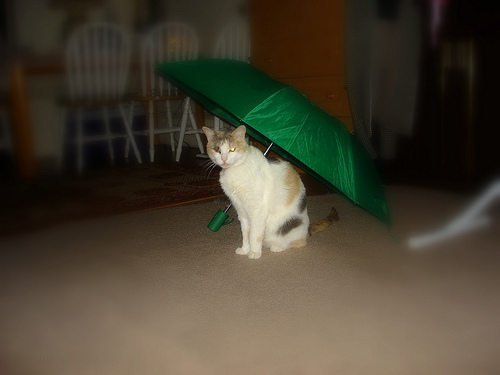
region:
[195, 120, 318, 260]
white cat with red and grey spots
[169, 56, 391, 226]
a bright kelly green umbrella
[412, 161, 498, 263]
front leg of an ironing board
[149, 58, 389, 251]
cat sits under an umbrella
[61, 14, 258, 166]
white side chairs with natural wood seats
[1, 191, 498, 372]
a beige area rug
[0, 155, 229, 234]
a red patterned area rug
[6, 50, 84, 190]
the end of a dining table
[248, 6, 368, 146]
a chest of drawers with wood knobs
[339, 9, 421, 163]
a grey jacket on a hanger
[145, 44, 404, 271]
a cat under an umbrella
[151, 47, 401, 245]
the umbrella is bright green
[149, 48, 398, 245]
the umbrella is a collapsible kind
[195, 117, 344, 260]
the cat is mostly white, with brown and gray spots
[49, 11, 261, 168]
wooden chairs with white backs behind the cat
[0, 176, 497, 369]
cat is sitting on a big open stretch of carpet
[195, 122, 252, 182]
cat has white whiskers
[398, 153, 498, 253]
the leg of another piece of furniture off to the right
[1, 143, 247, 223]
the floor looks like patterned lineoleum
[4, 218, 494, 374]
the carpet is beige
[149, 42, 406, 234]
open green umbrella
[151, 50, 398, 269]
cat standing under open green umbrella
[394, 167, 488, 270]
white light reflecting on tan floor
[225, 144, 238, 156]
yellow cat eye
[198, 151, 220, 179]
white cat whiskers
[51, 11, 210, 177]
white and wood chairs at table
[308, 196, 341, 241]
cat tail on floor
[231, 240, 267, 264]
two white cat paws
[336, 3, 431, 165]
grey garment hanging up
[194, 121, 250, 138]
two cat ears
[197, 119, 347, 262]
Cat on the ground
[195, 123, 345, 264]
Cat is on the ground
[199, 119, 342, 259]
Cat on the carpet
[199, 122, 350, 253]
Cat is on the carpet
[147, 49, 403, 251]
Umbrella on the ground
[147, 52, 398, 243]
Umbrella is on the ground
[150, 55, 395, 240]
Umbrella on the carpet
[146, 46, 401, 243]
Umbrella is on the carpet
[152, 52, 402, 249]
Green umbrella on the carpet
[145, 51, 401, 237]
Green umbrella is on the carpet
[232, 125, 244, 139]
ear of the cat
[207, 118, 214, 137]
ear of the cat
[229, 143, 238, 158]
eye of the cat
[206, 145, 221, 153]
eye of the cat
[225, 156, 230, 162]
nose of the cat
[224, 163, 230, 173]
mouth of the cat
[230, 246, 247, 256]
paw of the cat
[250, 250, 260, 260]
paw of the cat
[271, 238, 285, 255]
paw of the cat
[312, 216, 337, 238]
tail of the cat